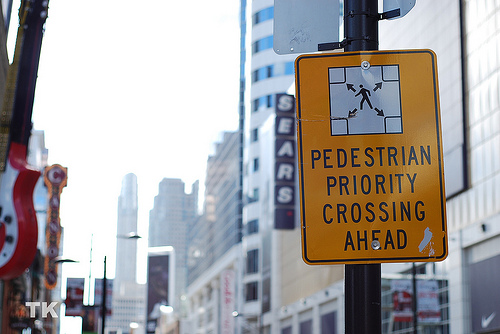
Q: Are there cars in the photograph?
A: No, there are no cars.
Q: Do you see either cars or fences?
A: No, there are no cars or fences.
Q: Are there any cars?
A: No, there are no cars.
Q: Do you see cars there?
A: No, there are no cars.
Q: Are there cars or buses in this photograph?
A: No, there are no cars or buses.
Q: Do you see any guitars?
A: Yes, there is a guitar.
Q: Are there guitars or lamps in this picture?
A: Yes, there is a guitar.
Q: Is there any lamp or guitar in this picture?
A: Yes, there is a guitar.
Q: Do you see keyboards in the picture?
A: No, there are no keyboards.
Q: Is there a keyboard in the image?
A: No, there are no keyboards.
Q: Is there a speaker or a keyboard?
A: No, there are no keyboards or speakers.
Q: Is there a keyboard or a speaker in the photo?
A: No, there are no keyboards or speakers.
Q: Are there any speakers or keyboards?
A: No, there are no keyboards or speakers.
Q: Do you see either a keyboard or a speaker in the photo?
A: No, there are no keyboards or speakers.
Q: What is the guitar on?
A: The guitar is on the sign.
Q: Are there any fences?
A: No, there are no fences.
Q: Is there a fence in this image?
A: No, there are no fences.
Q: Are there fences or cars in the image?
A: No, there are no fences or cars.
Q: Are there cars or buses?
A: No, there are no cars or buses.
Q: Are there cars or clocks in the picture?
A: No, there are no cars or clocks.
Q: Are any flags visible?
A: Yes, there is a flag.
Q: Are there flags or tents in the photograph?
A: Yes, there is a flag.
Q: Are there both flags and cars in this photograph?
A: No, there is a flag but no cars.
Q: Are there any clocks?
A: No, there are no clocks.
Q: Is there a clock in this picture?
A: No, there are no clocks.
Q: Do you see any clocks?
A: No, there are no clocks.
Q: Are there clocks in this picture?
A: No, there are no clocks.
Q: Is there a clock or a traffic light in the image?
A: No, there are no clocks or traffic lights.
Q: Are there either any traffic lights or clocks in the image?
A: No, there are no clocks or traffic lights.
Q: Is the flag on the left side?
A: Yes, the flag is on the left of the image.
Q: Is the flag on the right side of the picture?
A: No, the flag is on the left of the image.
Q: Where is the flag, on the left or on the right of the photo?
A: The flag is on the left of the image.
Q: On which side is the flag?
A: The flag is on the left of the image.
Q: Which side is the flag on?
A: The flag is on the left of the image.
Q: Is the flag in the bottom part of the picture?
A: Yes, the flag is in the bottom of the image.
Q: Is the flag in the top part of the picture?
A: No, the flag is in the bottom of the image.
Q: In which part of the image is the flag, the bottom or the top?
A: The flag is in the bottom of the image.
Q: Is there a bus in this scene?
A: No, there are no buses.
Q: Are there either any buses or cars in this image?
A: No, there are no buses or cars.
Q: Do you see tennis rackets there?
A: No, there are no tennis rackets.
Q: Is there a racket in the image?
A: No, there are no rackets.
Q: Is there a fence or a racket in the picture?
A: No, there are no rackets or fences.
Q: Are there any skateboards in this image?
A: No, there are no skateboards.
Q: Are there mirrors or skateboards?
A: No, there are no skateboards or mirrors.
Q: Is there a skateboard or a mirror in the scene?
A: No, there are no skateboards or mirrors.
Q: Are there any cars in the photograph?
A: No, there are no cars.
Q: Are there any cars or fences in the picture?
A: No, there are no cars or fences.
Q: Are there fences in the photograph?
A: No, there are no fences.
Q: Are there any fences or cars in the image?
A: No, there are no fences or cars.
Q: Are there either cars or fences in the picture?
A: No, there are no fences or cars.